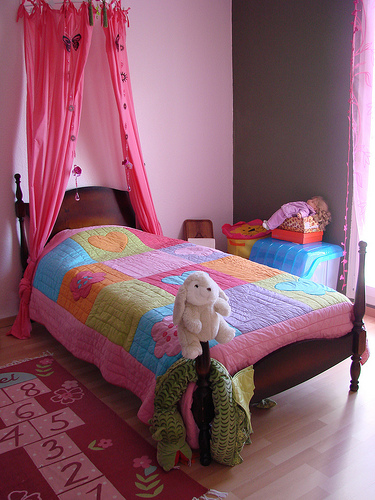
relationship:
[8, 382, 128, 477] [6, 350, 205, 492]
hopscotch pattern on rug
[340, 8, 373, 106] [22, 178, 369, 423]
pink drapes above bed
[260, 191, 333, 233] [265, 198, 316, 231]
toy doll with pink clothes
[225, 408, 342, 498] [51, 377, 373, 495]
floorboards cover floor